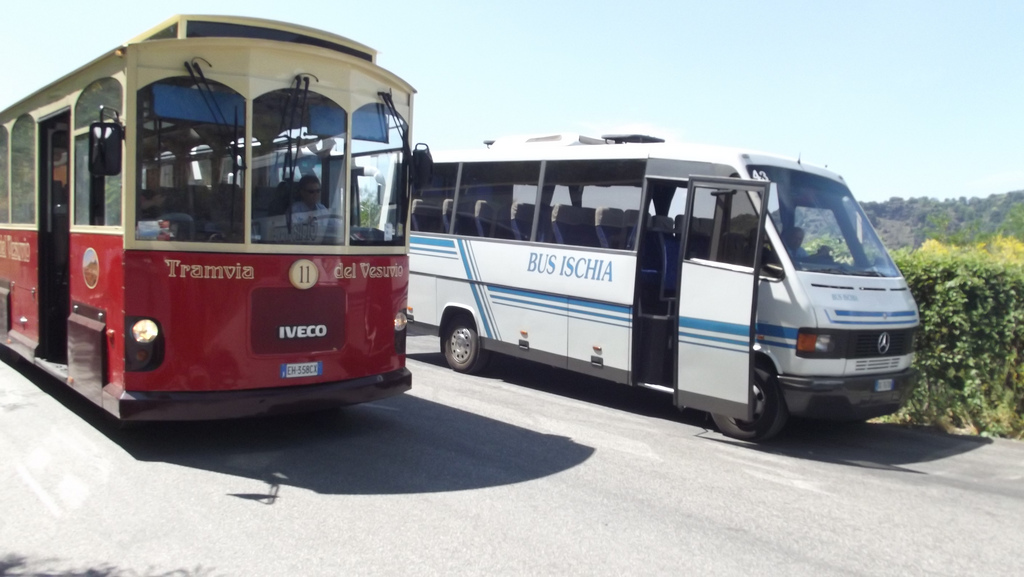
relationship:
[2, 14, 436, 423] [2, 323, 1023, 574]
bus on road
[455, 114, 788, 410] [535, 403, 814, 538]
bus on road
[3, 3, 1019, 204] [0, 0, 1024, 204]
clouds in clouds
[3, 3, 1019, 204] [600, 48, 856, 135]
clouds in sky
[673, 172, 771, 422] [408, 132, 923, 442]
door on bus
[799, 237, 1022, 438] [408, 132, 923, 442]
bush behind bus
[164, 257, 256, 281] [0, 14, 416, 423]
writing on bus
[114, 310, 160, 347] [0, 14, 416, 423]
headlight on bus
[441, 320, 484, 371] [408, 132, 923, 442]
tire on bus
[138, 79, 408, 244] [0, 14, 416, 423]
windshield on bus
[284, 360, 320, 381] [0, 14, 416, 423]
license plate on bus